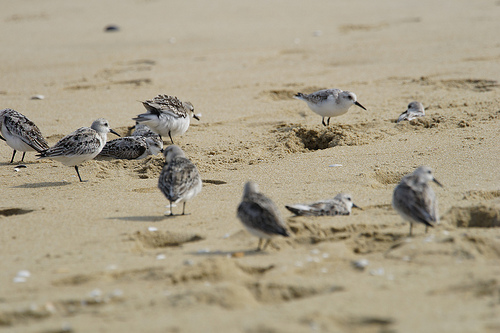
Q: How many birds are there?
A: 10.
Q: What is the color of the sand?
A: Brown.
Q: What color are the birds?
A: Grey and white.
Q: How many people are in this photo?
A: Zero.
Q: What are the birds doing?
A: Walking.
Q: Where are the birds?
A: On the sand.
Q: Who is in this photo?
A: No one.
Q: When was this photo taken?
A: Daytime.